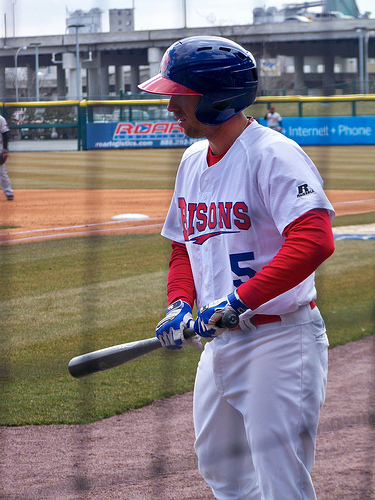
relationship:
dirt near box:
[3, 334, 369, 500] [2, 187, 158, 243]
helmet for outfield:
[133, 34, 260, 129] [1, 3, 369, 465]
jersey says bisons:
[160, 129, 340, 315] [176, 191, 254, 250]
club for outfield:
[67, 324, 203, 386] [1, 3, 369, 465]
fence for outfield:
[3, 97, 373, 153] [1, 3, 369, 465]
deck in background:
[5, 21, 370, 116] [1, 1, 373, 150]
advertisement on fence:
[103, 113, 204, 152] [3, 97, 373, 153]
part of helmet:
[136, 73, 198, 100] [133, 34, 260, 129]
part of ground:
[3, 184, 374, 247] [5, 152, 371, 498]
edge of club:
[67, 320, 162, 362] [67, 324, 203, 386]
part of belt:
[306, 297, 318, 309] [205, 301, 325, 327]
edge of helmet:
[135, 86, 199, 99] [133, 34, 260, 129]